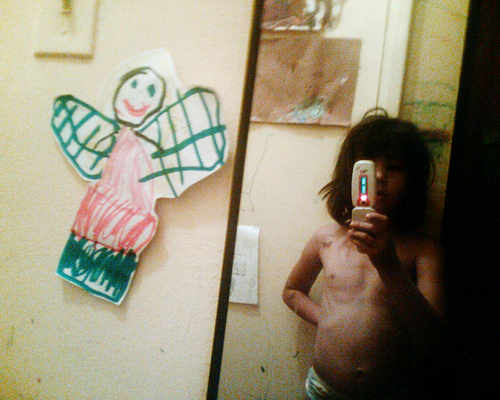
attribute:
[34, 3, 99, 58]
light switch — white, electrical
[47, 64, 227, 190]
angel — green, pink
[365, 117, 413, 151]
hair — unkempt, brown, dark, shoulder length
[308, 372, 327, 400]
underware — turquoise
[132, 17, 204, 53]
wall — white, off white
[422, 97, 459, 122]
wall — green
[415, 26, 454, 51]
wall — peach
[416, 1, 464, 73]
curtain — yellow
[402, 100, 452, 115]
stripes — green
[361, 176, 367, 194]
light — blue